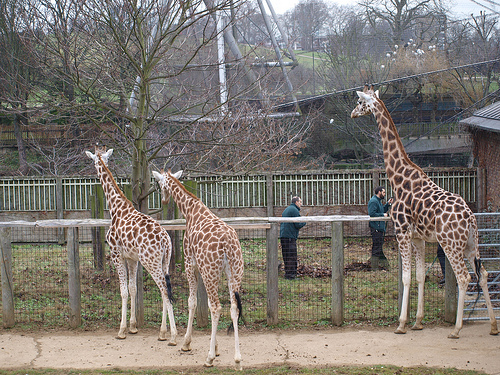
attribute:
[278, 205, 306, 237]
jacket — green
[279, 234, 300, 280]
pants — black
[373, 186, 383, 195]
hair — black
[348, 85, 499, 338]
giraffe — brown, white, here, side by side, standing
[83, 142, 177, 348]
giraffe — here, looking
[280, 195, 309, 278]
person — here, raking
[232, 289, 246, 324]
tail — black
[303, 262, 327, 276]
leaves — brown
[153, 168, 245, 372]
giraffe — here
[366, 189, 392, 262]
person — here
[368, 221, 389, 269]
pants — black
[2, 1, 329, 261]
tree — here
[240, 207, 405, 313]
fence — wooden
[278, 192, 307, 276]
man — standing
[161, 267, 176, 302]
tail — black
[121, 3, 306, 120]
tower — metal